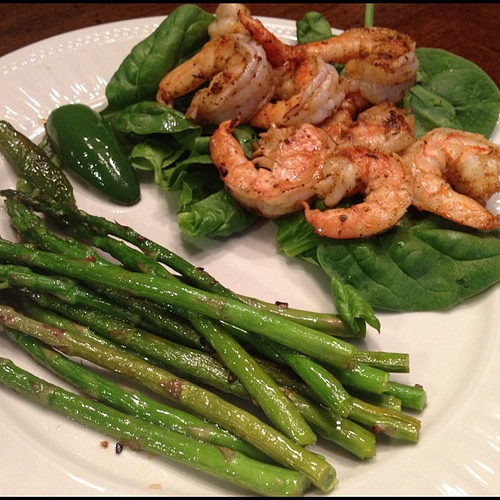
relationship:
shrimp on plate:
[298, 146, 413, 241] [0, 0, 499, 499]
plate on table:
[0, 0, 499, 499] [1, 0, 498, 87]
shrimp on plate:
[292, 25, 421, 108] [0, 0, 499, 499]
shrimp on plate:
[402, 124, 497, 235] [0, 0, 499, 499]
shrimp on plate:
[207, 120, 334, 221] [0, 0, 499, 499]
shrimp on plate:
[250, 51, 345, 126] [0, 0, 499, 499]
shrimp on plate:
[155, 26, 273, 126] [0, 0, 499, 499]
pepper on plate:
[54, 98, 129, 211] [0, 0, 499, 499]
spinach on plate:
[98, 0, 498, 341] [0, 0, 499, 499]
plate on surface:
[0, 0, 499, 499] [1, 3, 498, 88]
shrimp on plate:
[125, 7, 499, 255] [15, 12, 487, 472]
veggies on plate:
[6, 145, 416, 485] [15, 12, 487, 472]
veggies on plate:
[58, 91, 493, 271] [15, 12, 487, 472]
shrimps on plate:
[184, 41, 465, 232] [388, 310, 489, 384]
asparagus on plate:
[47, 244, 256, 443] [388, 310, 489, 384]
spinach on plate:
[104, 144, 256, 237] [388, 310, 489, 384]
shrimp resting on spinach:
[164, 16, 495, 244] [98, 0, 498, 341]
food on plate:
[46, 25, 497, 352] [0, 0, 499, 499]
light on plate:
[440, 477, 458, 498] [462, 346, 492, 450]